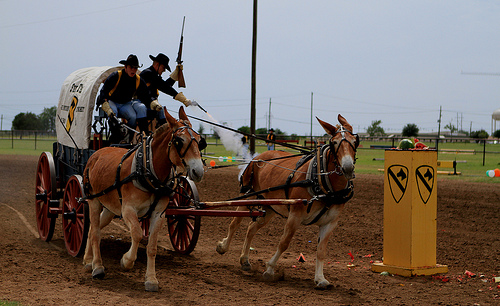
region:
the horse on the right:
[214, 114, 361, 290]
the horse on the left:
[72, 106, 203, 290]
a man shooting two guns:
[142, 14, 213, 119]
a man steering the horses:
[98, 54, 139, 145]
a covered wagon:
[35, 64, 201, 256]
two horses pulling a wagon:
[80, 104, 360, 288]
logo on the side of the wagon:
[58, 83, 85, 134]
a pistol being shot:
[190, 97, 208, 115]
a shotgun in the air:
[175, 16, 190, 88]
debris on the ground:
[338, 244, 498, 295]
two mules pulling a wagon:
[13, 35, 385, 304]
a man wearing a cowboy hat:
[89, 43, 140, 110]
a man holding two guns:
[145, 12, 201, 117]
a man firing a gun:
[138, 42, 203, 121]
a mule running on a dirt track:
[206, 110, 361, 285]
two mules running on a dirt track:
[22, 102, 374, 303]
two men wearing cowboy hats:
[101, 49, 172, 104]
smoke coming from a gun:
[156, 67, 247, 174]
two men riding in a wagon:
[71, 34, 200, 151]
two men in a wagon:
[48, 38, 219, 274]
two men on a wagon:
[94, 41, 208, 143]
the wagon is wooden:
[16, 40, 211, 269]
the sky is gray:
[319, 17, 430, 49]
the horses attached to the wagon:
[81, 113, 385, 295]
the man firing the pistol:
[141, 15, 213, 114]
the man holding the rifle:
[145, 15, 195, 105]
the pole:
[246, 0, 274, 155]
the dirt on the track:
[23, 165, 490, 304]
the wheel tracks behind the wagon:
[7, 198, 47, 239]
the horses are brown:
[23, 127, 375, 289]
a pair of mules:
[80, 107, 368, 279]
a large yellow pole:
[371, 139, 458, 284]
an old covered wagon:
[22, 64, 211, 259]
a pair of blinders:
[166, 131, 214, 156]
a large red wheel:
[21, 145, 60, 242]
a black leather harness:
[69, 135, 185, 214]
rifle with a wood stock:
[173, 16, 191, 92]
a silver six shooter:
[181, 99, 212, 116]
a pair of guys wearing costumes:
[92, 34, 195, 144]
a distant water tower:
[486, 105, 499, 139]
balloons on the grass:
[479, 156, 497, 187]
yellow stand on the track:
[365, 128, 452, 301]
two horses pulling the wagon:
[54, 84, 365, 302]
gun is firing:
[183, 95, 258, 188]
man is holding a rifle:
[159, 16, 199, 91]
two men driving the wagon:
[102, 45, 209, 138]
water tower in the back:
[485, 105, 499, 136]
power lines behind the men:
[292, 92, 498, 147]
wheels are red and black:
[39, 155, 126, 294]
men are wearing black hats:
[116, 50, 199, 88]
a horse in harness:
[57, 129, 186, 246]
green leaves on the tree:
[406, 121, 418, 127]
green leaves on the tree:
[33, 105, 55, 132]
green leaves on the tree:
[17, 119, 43, 136]